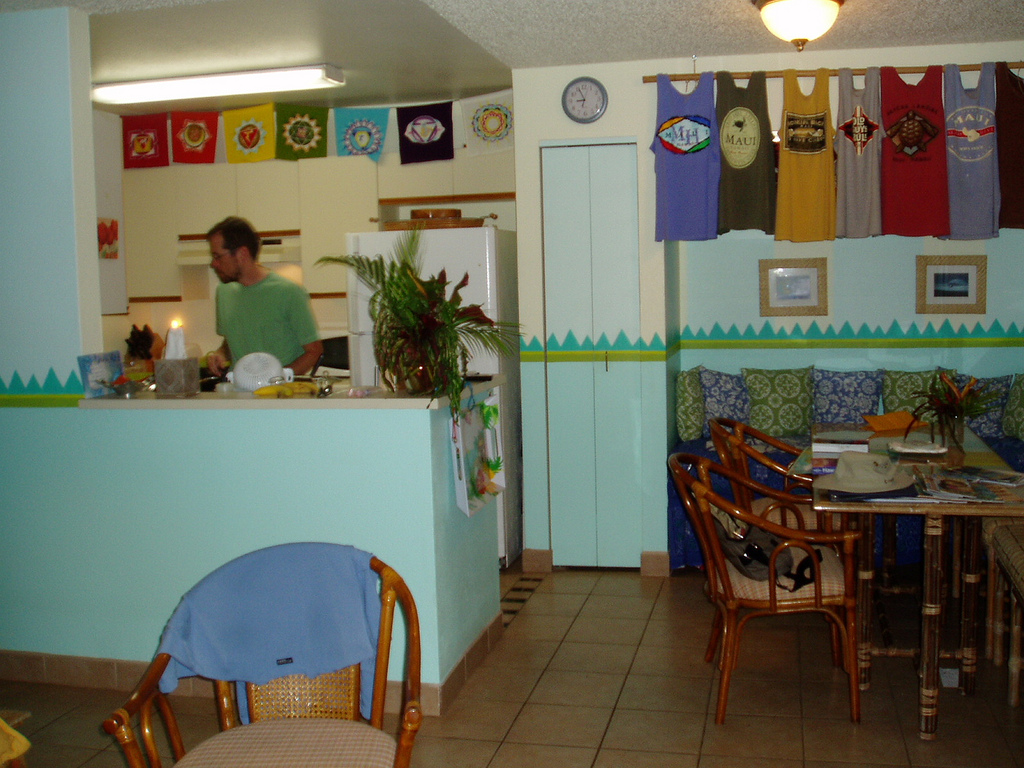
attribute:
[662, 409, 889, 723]
set — chairs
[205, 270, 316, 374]
shirt — green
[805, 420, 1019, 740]
table — brown, dining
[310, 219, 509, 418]
plant — fern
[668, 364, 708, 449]
pillow — green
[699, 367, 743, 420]
pillow — blue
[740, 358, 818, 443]
pillow — green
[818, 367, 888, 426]
pillow — blue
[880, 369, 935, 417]
pillow — green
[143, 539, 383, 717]
shirt — blue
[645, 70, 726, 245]
shirt — purple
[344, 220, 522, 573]
refrigerator — white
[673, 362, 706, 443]
pillow — green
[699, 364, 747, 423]
pillow — blue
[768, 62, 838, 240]
shirt — yellow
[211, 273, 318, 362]
shirt — green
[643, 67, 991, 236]
shirts — a row